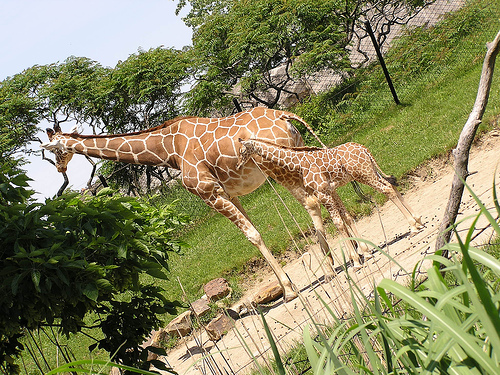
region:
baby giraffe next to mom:
[233, 129, 443, 275]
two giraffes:
[31, 100, 438, 304]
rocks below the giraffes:
[141, 220, 286, 374]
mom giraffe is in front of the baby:
[43, 114, 434, 316]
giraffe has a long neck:
[27, 110, 189, 183]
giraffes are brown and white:
[32, 97, 447, 312]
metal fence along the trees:
[286, 8, 494, 115]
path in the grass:
[124, 135, 498, 373]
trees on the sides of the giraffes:
[0, 0, 369, 140]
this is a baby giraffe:
[235, 133, 417, 278]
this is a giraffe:
[39, 105, 332, 284]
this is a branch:
[267, 17, 381, 109]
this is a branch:
[200, 7, 290, 84]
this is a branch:
[74, 219, 171, 372]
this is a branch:
[19, 206, 106, 342]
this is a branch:
[39, 62, 101, 119]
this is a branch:
[0, 78, 64, 173]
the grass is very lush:
[370, 110, 426, 170]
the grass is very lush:
[403, 57, 481, 127]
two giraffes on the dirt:
[28, 98, 439, 294]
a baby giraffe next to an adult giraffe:
[37, 95, 443, 308]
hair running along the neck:
[246, 133, 328, 154]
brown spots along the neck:
[65, 123, 178, 170]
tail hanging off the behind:
[281, 109, 333, 151]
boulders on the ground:
[113, 263, 293, 374]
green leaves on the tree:
[3, 149, 193, 374]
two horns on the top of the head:
[43, 120, 63, 137]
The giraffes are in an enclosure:
[25, 47, 485, 367]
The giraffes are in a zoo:
[15, 50, 486, 367]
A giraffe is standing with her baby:
[32, 51, 459, 328]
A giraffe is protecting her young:
[30, 41, 450, 333]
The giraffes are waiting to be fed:
[22, 73, 439, 333]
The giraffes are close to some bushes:
[26, 77, 441, 290]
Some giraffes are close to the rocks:
[28, 56, 431, 356]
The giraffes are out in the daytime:
[26, 75, 441, 322]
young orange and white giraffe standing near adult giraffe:
[226, 128, 429, 288]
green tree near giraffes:
[1, 143, 203, 373]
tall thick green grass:
[286, 163, 498, 373]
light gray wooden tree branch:
[426, 26, 497, 356]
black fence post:
[358, 15, 406, 115]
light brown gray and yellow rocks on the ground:
[98, 272, 295, 374]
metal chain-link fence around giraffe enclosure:
[0, 0, 498, 295]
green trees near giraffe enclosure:
[0, 0, 452, 328]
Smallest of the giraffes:
[232, 132, 423, 274]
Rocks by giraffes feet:
[207, 276, 286, 344]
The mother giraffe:
[45, 102, 365, 313]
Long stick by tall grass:
[425, 25, 498, 280]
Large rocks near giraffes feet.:
[102, 270, 282, 369]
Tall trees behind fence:
[2, 2, 439, 219]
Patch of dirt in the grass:
[132, 131, 498, 373]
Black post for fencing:
[360, 14, 412, 111]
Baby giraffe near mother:
[234, 135, 432, 270]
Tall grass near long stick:
[214, 251, 497, 373]